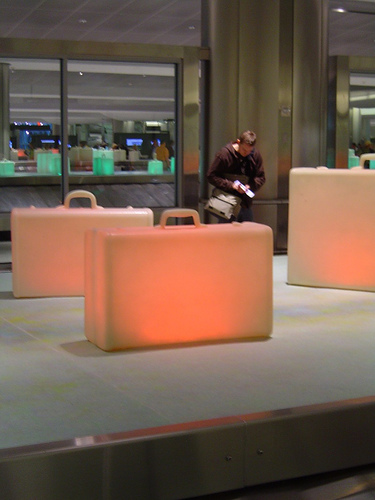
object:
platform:
[1, 249, 375, 497]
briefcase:
[83, 204, 274, 345]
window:
[0, 57, 66, 217]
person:
[207, 130, 267, 232]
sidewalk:
[0, 238, 375, 450]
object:
[235, 177, 259, 203]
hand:
[228, 179, 246, 194]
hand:
[243, 185, 254, 194]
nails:
[222, 450, 231, 462]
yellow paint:
[1, 303, 46, 330]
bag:
[203, 176, 251, 221]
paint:
[10, 365, 82, 409]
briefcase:
[10, 186, 155, 303]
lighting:
[188, 22, 194, 31]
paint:
[274, 305, 362, 340]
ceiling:
[0, 0, 375, 57]